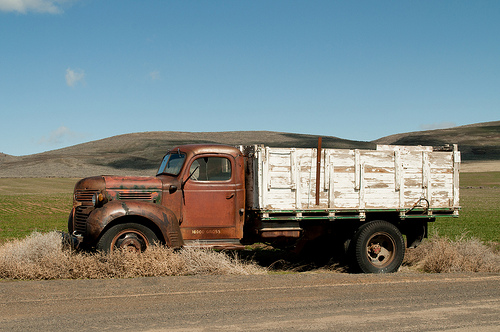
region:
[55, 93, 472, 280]
Truck parked on the road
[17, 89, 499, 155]
VEry tall hill tops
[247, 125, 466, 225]
White wood on back of truckj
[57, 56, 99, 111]
White cloud in the sky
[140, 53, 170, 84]
White cloud in the sky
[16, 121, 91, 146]
White cloud in the sky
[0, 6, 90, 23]
White cloud in the sky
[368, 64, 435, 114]
Part of the blue sky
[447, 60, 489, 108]
Part of the blue sky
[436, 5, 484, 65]
Part of the blue sky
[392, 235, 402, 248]
part of a wheel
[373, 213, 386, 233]
edge of a wheel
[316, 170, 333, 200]
part of a board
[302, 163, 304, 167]
part of a truck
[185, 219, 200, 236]
part of a door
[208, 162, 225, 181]
part of a window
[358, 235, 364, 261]
part of a wheel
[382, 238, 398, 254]
part of a wheel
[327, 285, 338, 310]
part of a road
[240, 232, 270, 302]
edge of a road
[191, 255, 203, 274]
part of a bush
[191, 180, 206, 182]
part of a window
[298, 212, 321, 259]
side of a truck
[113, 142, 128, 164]
edge of a hill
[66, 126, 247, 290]
the truck is rusty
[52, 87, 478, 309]
the truck is parked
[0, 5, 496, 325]
an old abandoned truck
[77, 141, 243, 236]
an orange truck cab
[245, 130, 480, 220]
old white truck bed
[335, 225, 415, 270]
the black truck wheels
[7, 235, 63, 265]
some dead dry grass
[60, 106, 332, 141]
grey hills in the background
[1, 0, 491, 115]
the deep blue skies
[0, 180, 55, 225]
green grass and red dirt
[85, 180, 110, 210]
an old headlight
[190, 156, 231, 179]
the door window